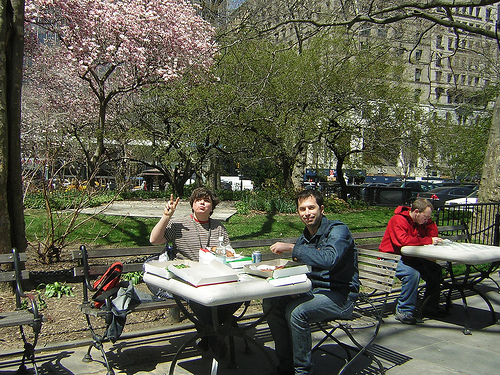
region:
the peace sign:
[159, 194, 185, 216]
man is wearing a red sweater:
[381, 218, 416, 253]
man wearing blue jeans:
[296, 301, 324, 319]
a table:
[208, 288, 234, 302]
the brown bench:
[75, 246, 136, 263]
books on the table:
[174, 261, 236, 283]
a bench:
[367, 258, 390, 293]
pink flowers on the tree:
[66, 25, 208, 77]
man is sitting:
[387, 202, 441, 248]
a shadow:
[378, 342, 408, 372]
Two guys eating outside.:
[131, 187, 388, 364]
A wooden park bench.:
[72, 212, 497, 358]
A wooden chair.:
[311, 234, 408, 373]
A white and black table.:
[144, 250, 319, 373]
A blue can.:
[252, 249, 262, 263]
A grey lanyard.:
[190, 211, 215, 251]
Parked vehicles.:
[277, 150, 497, 207]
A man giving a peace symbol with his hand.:
[147, 187, 254, 263]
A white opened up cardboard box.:
[142, 256, 239, 288]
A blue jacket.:
[282, 217, 363, 297]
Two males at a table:
[137, 186, 359, 373]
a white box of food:
[242, 256, 312, 278]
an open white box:
[142, 258, 243, 288]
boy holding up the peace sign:
[148, 186, 224, 243]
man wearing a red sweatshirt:
[375, 197, 443, 256]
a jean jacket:
[102, 281, 143, 351]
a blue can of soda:
[248, 248, 265, 266]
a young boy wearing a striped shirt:
[149, 183, 233, 264]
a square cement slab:
[64, 186, 249, 223]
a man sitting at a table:
[375, 195, 497, 332]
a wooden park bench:
[70, 245, 188, 373]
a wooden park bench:
[0, 249, 42, 373]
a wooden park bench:
[306, 244, 399, 374]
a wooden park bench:
[352, 220, 474, 312]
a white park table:
[140, 258, 312, 372]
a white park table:
[401, 240, 499, 337]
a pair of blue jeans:
[263, 290, 355, 372]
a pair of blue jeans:
[396, 258, 445, 308]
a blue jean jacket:
[291, 220, 359, 294]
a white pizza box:
[243, 257, 310, 277]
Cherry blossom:
[13, 3, 228, 148]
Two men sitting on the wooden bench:
[78, 148, 402, 370]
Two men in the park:
[63, 153, 413, 369]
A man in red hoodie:
[385, 175, 499, 312]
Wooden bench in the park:
[341, 245, 403, 367]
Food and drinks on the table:
[136, 238, 321, 313]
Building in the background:
[216, 3, 493, 197]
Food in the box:
[244, 253, 307, 285]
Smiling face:
[283, 186, 330, 229]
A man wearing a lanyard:
[183, 187, 222, 249]